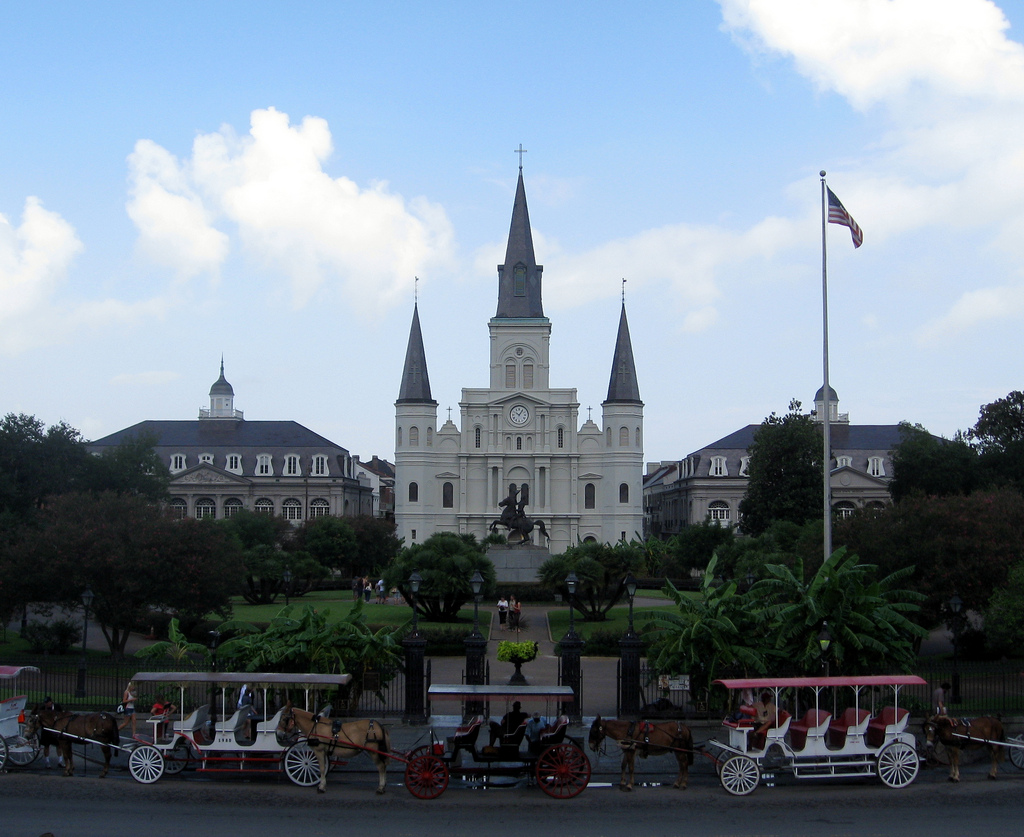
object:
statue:
[488, 491, 551, 546]